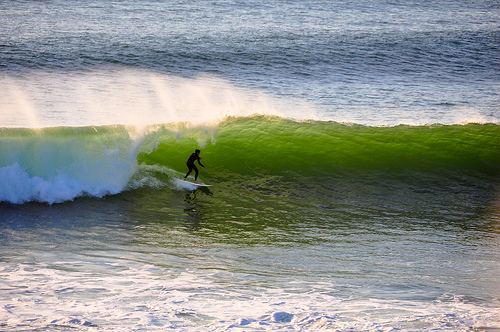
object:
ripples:
[18, 284, 78, 316]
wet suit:
[185, 154, 204, 170]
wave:
[329, 26, 399, 116]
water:
[261, 12, 450, 108]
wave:
[1, 110, 494, 214]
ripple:
[143, 165, 169, 185]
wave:
[387, 301, 442, 326]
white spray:
[1, 75, 315, 125]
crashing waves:
[3, 115, 496, 205]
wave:
[46, 55, 188, 225]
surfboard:
[178, 171, 213, 188]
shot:
[6, 4, 494, 324]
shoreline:
[6, 311, 491, 330]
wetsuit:
[184, 153, 205, 181]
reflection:
[182, 193, 206, 222]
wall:
[229, 69, 301, 104]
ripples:
[339, 298, 498, 328]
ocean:
[6, 8, 498, 114]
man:
[182, 149, 206, 185]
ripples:
[93, 291, 313, 329]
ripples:
[7, 272, 164, 305]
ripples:
[158, 220, 498, 287]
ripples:
[283, 31, 457, 95]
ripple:
[274, 44, 446, 84]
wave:
[0, 27, 499, 80]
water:
[308, 165, 389, 214]